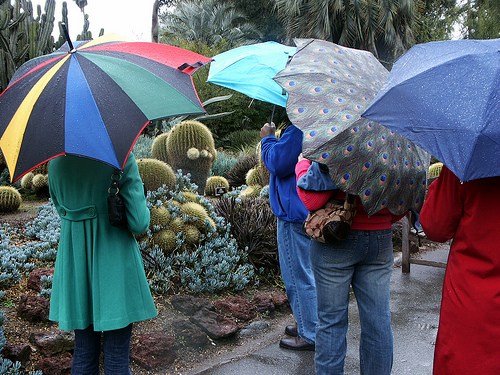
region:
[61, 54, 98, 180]
Blue stripe on umbrella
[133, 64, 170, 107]
Green stripe on umbrella.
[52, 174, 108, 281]
Woman wearing green coat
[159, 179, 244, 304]
Green and blue bushes.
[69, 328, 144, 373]
Woman wears blue jeans.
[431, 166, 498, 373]
Woman wears long red coat.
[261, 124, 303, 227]
Man wears blue coat.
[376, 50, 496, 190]
Blue umberella over ladies head.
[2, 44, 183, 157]
Rainbow striped umbrella over lady head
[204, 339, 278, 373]
Wet ground from the rain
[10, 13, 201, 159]
colorful umbrella over person's head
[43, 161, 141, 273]
blue jacket of person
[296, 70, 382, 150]
peacock umbrella of person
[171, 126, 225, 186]
cacti in front of people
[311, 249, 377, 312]
blue pants on person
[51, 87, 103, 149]
blue part of umbrella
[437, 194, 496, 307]
red jacket on person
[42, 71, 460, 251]
group of people with umbrellas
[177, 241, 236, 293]
blue plants in front of people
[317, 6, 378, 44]
tree next to people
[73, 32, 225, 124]
multicolored umbrella for rain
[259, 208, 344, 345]
blue pants on visitor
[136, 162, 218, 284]
cactus plants in the zoo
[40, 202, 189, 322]
green trenchcoat of lady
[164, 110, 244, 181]
big cactus in distance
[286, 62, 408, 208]
peacock umbrella woman is holding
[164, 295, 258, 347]
hard surface that cacti are on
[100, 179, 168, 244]
black purse of woman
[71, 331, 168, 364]
dark jeans of woman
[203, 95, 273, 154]
dark trees in distance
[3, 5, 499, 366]
people are standing next to the garden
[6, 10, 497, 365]
the people are holding umbrellas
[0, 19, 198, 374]
a woman holding a striped umbrella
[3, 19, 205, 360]
the woman with the striped umbrella is wearing a teal coat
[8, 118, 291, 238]
cactus plants are in the garden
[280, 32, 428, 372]
a person holds an umbrella witha peacock pattern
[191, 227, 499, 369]
the ground is wet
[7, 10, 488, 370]
rain is gathering on the umbrellas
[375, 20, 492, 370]
the woman in the red coat has a blue umbrella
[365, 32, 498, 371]
the person with the blue umbrella is wearing red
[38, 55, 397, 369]
three people wearing blue jeans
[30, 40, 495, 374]
four people with umbrellas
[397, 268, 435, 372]
wet concrete sidewalk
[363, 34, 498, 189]
one blue umbrella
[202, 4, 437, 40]
palm trees in background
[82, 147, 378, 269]
two people with purses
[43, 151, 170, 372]
woman with black purse and green sweater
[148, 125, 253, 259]
green cactus plant display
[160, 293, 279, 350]
brown lava rock on ground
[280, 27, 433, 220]
peacock feather pattern on umbrella